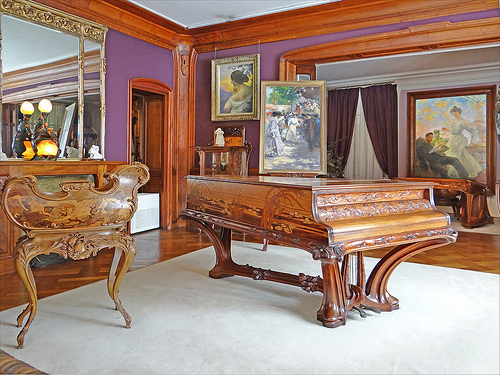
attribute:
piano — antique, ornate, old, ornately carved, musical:
[179, 173, 459, 329]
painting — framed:
[208, 53, 261, 123]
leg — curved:
[112, 228, 136, 329]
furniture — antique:
[0, 161, 150, 350]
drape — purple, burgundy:
[360, 84, 397, 178]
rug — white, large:
[1, 239, 500, 375]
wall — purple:
[192, 8, 500, 177]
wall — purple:
[104, 26, 176, 229]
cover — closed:
[322, 210, 450, 245]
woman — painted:
[223, 70, 253, 114]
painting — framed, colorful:
[414, 93, 488, 187]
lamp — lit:
[30, 97, 62, 159]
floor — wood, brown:
[348, 229, 499, 275]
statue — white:
[86, 144, 104, 161]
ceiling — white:
[130, 1, 340, 29]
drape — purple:
[328, 86, 360, 171]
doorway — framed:
[131, 87, 165, 233]